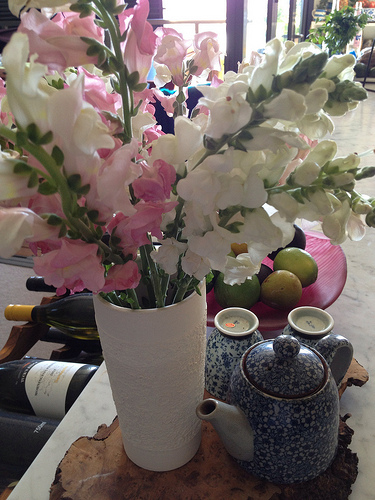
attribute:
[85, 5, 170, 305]
stem — green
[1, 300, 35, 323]
cap — yellow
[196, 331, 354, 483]
kettle — blue, floral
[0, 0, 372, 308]
flowers — white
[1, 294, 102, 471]
bottles — wine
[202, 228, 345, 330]
plate — pink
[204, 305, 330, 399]
tea cups — upside down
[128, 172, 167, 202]
petals — pink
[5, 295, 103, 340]
bottle — wine, labeless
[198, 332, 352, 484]
teapot — blue and white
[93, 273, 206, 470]
vase — white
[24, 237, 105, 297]
flower — pink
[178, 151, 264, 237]
flower — white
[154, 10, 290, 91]
window — background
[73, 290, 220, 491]
vase — white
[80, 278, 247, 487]
vase — plaster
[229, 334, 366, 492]
teapot — speckled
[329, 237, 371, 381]
counter — marble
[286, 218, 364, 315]
dish — pink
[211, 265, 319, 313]
fruit — green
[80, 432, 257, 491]
mat — brown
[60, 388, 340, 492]
wood — brown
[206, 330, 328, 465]
tea pot — blue, white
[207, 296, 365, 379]
cups — white, blue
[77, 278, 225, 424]
vase — white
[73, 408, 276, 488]
slab — wood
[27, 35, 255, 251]
flowers — pink, white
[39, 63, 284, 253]
flowers — white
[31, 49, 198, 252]
flowers — pink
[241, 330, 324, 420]
teapot — white, blue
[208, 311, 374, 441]
pot — blue, white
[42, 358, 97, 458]
table — white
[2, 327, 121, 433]
wine bottle — black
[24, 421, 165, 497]
wood — brown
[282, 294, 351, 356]
candle — blue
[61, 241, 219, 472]
vase — large, white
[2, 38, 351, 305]
flowers — white, pink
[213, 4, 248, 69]
column — purple